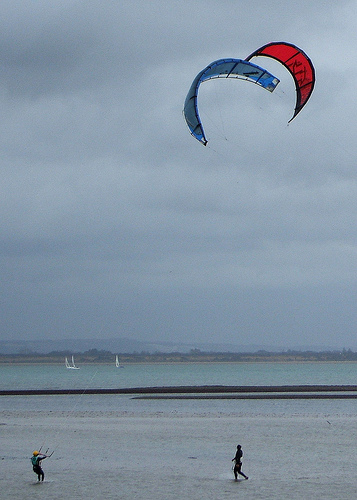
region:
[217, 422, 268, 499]
guy walking in shallow water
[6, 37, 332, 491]
kites flying over water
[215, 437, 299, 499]
guy watching the sky in water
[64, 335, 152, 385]
two sail boats sailing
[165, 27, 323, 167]
a blue parachute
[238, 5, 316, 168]
a red parachute in the sky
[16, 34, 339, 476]
guy getting ready to take off with parachutes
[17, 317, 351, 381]
mountains in the horizan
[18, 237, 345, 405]
a dark cloudy sky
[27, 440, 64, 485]
someone with a yellow helmet on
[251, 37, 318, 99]
Large kite flying in sky.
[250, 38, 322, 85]
Red kite flying in sky.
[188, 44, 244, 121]
Large kite flying in sky.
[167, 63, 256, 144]
Blue kite flying in sky.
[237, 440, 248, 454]
Person has dark hair.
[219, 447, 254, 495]
Person wearing dark clothing.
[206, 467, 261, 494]
Person walking in water.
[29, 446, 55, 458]
Person wearing yellow hat.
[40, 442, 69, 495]
Person holding onto handle connected to wires.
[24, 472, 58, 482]
Person standing in water.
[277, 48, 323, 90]
Red kite in sky.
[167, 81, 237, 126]
Blue kite in sky.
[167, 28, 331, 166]
2 large kites flying in sky.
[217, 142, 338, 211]
Wires connected to large kites.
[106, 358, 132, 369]
White boat in water.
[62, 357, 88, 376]
White boat in water.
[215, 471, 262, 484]
Person walking in water.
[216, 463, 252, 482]
Person wearing dark pants.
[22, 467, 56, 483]
Person holding onto kite wires.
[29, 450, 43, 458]
Person wearing yellow hat.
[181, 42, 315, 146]
Kites in the sky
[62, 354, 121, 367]
Boats in the water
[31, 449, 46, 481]
A person flying the kites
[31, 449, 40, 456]
The person is wearing a hat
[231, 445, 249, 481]
The person is walking in the water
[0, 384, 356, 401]
Strips of land between the bodies of water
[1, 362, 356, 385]
A body of water beneath the boats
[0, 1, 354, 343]
A cloudy sky above the water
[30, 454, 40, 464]
The person is wearing a backpack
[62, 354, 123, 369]
The boats have sails